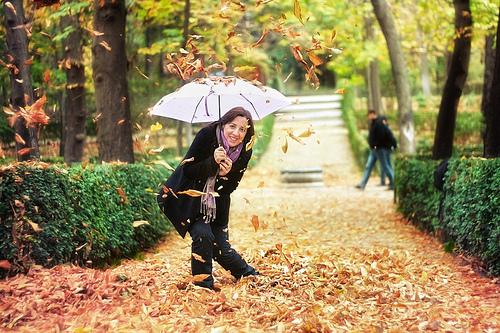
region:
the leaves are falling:
[32, 18, 319, 98]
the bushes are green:
[391, 163, 496, 248]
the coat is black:
[175, 140, 240, 224]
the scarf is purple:
[200, 133, 235, 217]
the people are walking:
[358, 105, 396, 189]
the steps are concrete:
[279, 88, 352, 130]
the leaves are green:
[296, 11, 391, 66]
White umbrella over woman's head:
[145, 73, 292, 123]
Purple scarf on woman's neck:
[213, 125, 241, 161]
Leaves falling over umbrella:
[126, 3, 346, 88]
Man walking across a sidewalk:
[355, 108, 392, 189]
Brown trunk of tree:
[86, 1, 131, 161]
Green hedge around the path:
[393, 140, 498, 271]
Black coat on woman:
[148, 120, 246, 236]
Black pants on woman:
[187, 219, 249, 274]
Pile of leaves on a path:
[269, 200, 474, 332]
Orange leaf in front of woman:
[177, 185, 202, 199]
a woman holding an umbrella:
[138, 56, 282, 287]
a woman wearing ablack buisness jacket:
[139, 65, 301, 312]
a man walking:
[355, 105, 400, 209]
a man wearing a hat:
[351, 106, 396, 206]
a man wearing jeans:
[350, 101, 400, 201]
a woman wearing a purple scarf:
[138, 67, 286, 281]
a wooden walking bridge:
[278, 76, 365, 183]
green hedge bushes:
[15, 130, 156, 264]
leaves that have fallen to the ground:
[258, 199, 435, 331]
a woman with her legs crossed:
[120, 55, 300, 300]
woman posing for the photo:
[155, 107, 260, 291]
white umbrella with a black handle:
[148, 77, 293, 150]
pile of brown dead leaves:
[1, 192, 498, 332]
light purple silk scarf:
[199, 124, 242, 222]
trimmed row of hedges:
[1, 152, 181, 281]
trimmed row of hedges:
[391, 145, 498, 282]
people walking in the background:
[356, 108, 399, 192]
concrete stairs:
[257, 90, 361, 167]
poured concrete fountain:
[278, 164, 325, 189]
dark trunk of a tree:
[428, 0, 471, 161]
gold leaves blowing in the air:
[155, 20, 325, 78]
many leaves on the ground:
[31, 268, 178, 323]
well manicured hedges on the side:
[441, 152, 495, 254]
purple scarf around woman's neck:
[201, 132, 241, 224]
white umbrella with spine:
[139, 56, 303, 124]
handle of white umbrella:
[211, 87, 225, 160]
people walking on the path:
[357, 109, 397, 195]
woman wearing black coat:
[139, 126, 254, 236]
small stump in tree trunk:
[83, 69, 123, 96]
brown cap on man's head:
[351, 100, 384, 117]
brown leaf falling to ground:
[250, 213, 261, 232]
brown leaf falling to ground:
[259, 219, 269, 229]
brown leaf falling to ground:
[275, 240, 285, 254]